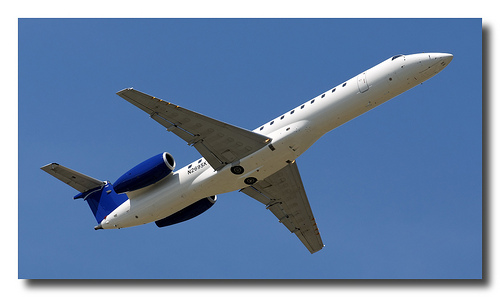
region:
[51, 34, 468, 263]
white and blue passenger jet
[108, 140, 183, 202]
blue jet engine with white trim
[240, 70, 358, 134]
windows on an aircraft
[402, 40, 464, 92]
nose cone of an airplant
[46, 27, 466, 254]
white airplane in blue sky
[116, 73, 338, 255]
wings on an aircraft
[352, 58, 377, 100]
closed door of an airplane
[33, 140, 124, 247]
tail wing of an aircraft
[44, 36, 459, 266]
airplane with landing gear up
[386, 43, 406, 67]
cockpit windshield of a jet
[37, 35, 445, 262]
white and blue airplane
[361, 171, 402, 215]
white clouds in blue sky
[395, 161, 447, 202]
white clouds in blue sky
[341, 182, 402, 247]
white clouds in blue sky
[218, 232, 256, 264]
white clouds in blue sky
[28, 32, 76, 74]
white clouds in blue sky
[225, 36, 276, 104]
white clouds in blue sky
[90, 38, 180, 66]
white clouds in blue sky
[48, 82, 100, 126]
white clouds in blue sky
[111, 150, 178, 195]
BLUE ENGINE ON PLANE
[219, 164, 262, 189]
LANDING GEAR IS UP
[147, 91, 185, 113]
ORANGE LIGHTS ON WING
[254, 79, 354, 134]
ROW OF ROUND WINDOWS ON PLANE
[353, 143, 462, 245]
CLEAR BLUE SKY AROUND PLANE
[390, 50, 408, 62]
GLASS WINDOW OF COCKPIT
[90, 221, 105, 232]
SILVER CONE ON REAR OF PLANE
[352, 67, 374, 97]
CLOSED DOOR ON SIDE OF PLANE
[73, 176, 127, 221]
ROYAL BLUE TRIM ON TAIL OF PLANE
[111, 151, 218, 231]
TWO LARGE JET ENGINES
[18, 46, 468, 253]
plane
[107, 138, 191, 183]
blue plane engine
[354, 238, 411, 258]
white clouds in blue sky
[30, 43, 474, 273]
This is an airplane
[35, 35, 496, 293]
This is an airplane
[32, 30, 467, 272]
This is an airplane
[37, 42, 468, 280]
This is an airplane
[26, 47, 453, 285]
This is an airplane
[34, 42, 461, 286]
This is an airplane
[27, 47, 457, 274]
This is an airplane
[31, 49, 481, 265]
This is an airplane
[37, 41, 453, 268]
This is an airplane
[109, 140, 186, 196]
blue jet engine on white plane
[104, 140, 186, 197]
blue jet engine on white plane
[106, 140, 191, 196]
blue jet engine on white plane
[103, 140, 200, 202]
blue jet engine on white plane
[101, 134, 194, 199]
blue jet engine on white plane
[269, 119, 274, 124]
plane has a window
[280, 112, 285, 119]
plane has a window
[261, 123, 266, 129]
plane has a window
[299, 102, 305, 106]
plane has a window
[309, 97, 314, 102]
plane has a window